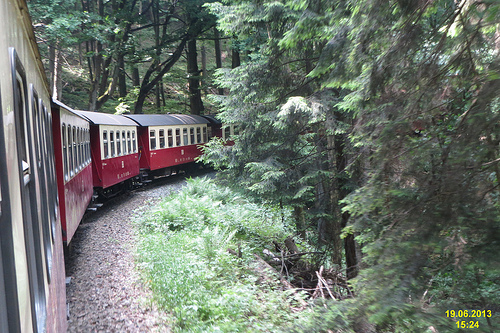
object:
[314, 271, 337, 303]
sticks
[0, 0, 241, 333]
train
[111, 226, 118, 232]
gravel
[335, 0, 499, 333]
trees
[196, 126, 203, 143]
windows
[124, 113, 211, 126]
roof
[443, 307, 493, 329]
lettering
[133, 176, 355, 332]
grass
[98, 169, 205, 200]
tracks